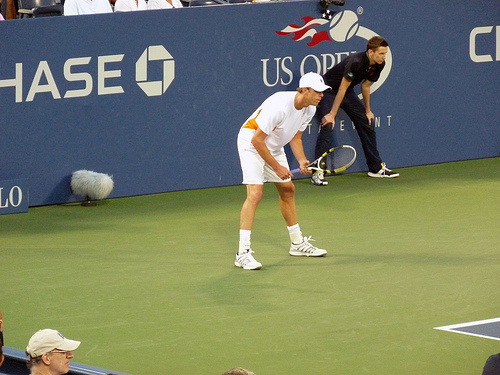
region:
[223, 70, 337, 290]
this is a tennis player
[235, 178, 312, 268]
these are the legs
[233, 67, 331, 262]
the player is bending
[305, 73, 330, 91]
this is s a cap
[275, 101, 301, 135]
this is the jersey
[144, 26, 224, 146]
this is the poster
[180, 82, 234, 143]
it is blue in color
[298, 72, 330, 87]
the cap is white in color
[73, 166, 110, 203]
this is a microphone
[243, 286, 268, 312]
part of a floor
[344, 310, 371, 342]
part of a ground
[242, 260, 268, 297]
edge of a shoe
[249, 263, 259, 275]
edge of a sole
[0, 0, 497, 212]
Blue wall with white writing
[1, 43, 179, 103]
Ad and logo for Chase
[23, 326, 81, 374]
Man in white hat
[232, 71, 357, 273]
Man in white tennis outfit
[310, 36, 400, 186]
Man standing on sidelines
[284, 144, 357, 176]
Man holding tennis racket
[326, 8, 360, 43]
Picture of white tennis ball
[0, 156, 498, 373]
Green colored tennis court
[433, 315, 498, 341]
White and blue painted tennis court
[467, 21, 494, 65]
White letter C on wall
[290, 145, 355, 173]
Racket being held by the tennis player.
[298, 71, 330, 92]
Hat on the tennis players head.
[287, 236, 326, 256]
Shoe on the tennis players left foot.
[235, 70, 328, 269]
Tennis player competing in a match.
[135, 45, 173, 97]
Logo for Chase bank.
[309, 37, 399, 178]
Referee for the tennis match.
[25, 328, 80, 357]
Hat on a spectator's head.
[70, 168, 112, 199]
Fluffy bag against the wall.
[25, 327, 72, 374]
Head and face of a spectator.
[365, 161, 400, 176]
Left shoe of the referee.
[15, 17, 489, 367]
Professional men's tennis match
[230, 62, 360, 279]
Man awaiting tennis serve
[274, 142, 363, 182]
Two hands grasping tennis racket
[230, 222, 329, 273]
White athletic socks and shoes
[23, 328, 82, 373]
Man in white cap and glasses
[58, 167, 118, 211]
Covered mike sitting on tennis court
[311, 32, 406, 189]
Ball boy in blue standing against wall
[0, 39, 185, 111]
Chase sponsorship logo on blue wall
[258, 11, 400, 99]
US Open tennis logo on wall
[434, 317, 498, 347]
Edge of white striped blue tennis court